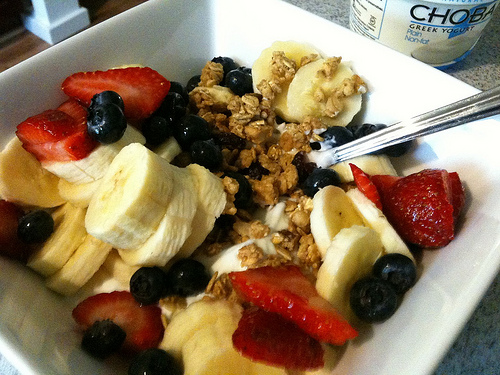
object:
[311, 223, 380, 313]
banana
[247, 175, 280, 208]
granola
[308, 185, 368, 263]
banana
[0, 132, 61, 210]
banana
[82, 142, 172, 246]
banana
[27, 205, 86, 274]
banana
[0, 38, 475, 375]
fruit plate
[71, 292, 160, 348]
strawberry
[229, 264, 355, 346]
strawberry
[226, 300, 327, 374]
strawberry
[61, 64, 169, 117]
strawberry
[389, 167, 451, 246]
strawberry